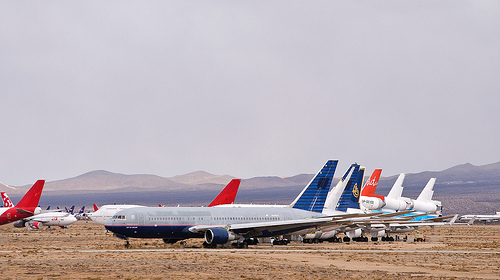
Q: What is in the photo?
A: Planes.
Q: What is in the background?
A: Mountains.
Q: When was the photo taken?
A: Morning.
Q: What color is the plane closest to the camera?
A: Grey.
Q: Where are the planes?
A: Desert.